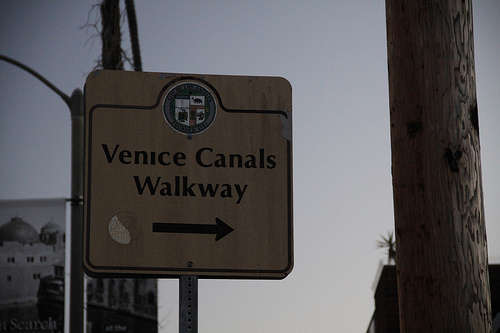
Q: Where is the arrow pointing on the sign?
A: To the right.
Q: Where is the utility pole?
A: On the right side of the picture.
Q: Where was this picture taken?
A: In Venice.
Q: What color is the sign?
A: Tan.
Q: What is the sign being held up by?
A: A metal pole.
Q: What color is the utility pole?
A: Dark brown and tan.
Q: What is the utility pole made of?
A: Wood.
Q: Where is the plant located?
A: On top of a building.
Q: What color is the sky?
A: Grayish blue.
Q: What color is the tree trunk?
A: Brown.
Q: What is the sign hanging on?
A: A metal pole.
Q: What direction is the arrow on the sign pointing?
A: To the right.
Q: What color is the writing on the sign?
A: Black.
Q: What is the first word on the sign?
A: Venice.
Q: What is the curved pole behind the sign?
A: A lamp post.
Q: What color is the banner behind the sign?
A: Black and white.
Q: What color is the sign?
A: Blue.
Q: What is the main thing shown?
A: Sign.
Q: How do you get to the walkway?
A: Follow the arrow.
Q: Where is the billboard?
A: Behind the sign.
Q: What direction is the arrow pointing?
A: To the right.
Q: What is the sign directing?
A: To the canal walkway.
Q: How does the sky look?
A: Clear.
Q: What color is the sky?
A: Gray.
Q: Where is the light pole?
A: Left of the sign.